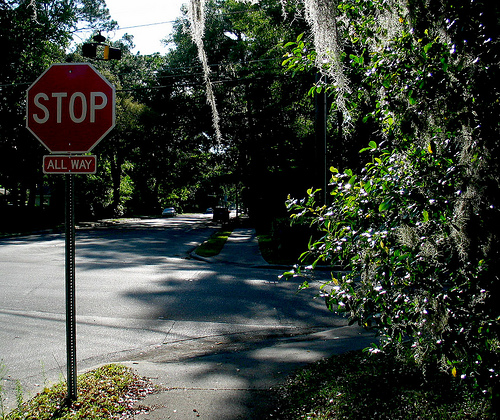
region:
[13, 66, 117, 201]
a stop sign on a post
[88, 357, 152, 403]
grass near the curb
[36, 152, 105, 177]
a red sign with white lettering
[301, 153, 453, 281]
green leaves on a tree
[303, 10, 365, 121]
Spanish moss hanging off of a tree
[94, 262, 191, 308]
the surface of a road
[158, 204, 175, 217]
a parked car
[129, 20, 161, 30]
suspended electrical wire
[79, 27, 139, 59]
a suspended traffic light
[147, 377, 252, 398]
the seam in a cement sidewalk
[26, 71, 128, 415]
The stop sign is on the corner of the curve.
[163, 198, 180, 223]
A car is parked in distance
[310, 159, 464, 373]
The tree is on the other side of the sidewalk.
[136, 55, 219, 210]
The trees are green.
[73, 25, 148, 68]
A red light is hanging in the middle.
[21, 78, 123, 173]
The stop sign is red.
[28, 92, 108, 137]
The letter on the stop sign is white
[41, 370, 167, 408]
The grass is on the curve of the sidewalk.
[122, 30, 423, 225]
Trees covering the street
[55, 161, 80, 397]
The pole is made out of steel.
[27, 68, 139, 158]
the sign says STOP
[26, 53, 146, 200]
the sign is red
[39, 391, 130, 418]
the grass is green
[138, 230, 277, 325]
shows on the street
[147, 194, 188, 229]
the car is parked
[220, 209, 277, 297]
the sidewalk is empty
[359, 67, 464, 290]
the bushes are green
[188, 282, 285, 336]
trees shadows are black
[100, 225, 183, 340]
the street is gray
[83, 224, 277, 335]
the street is empty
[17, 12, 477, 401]
A heavily shaded residential area.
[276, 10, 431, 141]
Spanish moss.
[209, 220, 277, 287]
A sidewalk.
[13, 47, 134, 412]
A stop sign attached to a metal pole.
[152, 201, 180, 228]
A parked car.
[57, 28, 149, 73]
A stoplight.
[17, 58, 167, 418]
A sign on the edge of the sidewalk.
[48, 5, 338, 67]
A two-way stop light attached to a power line.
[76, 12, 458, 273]
A shaded area with sunlight poking through.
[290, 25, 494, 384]
A large bush.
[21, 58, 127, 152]
Stop sign on green post.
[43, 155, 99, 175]
All way sign on green post.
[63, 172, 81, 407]
Green post holding stop sign up.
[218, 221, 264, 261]
Sidewalk leading up the block.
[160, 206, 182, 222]
Car parked on side of street.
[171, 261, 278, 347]
Street between each sidewalk.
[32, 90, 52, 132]
The letter S on the stop sign.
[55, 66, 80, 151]
Two screws on stop sign at top and bottom of sign.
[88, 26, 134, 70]
Traffic light hanging on wires above stop sign.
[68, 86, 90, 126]
The letter O on the stop sign.